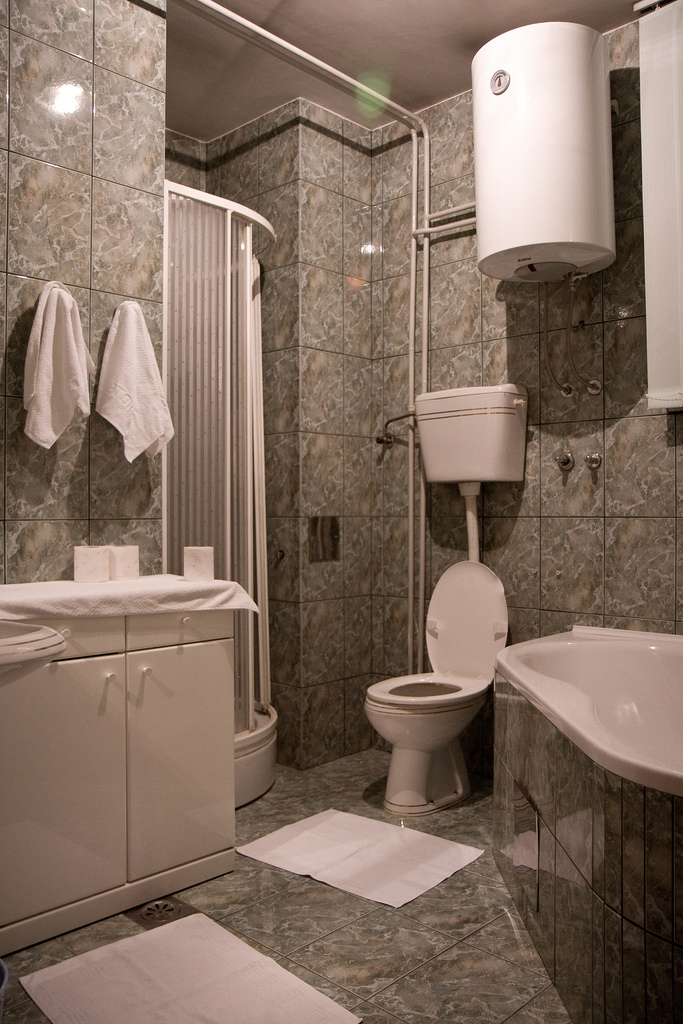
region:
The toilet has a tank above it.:
[361, 381, 528, 817]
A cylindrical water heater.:
[469, 21, 618, 284]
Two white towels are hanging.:
[22, 280, 174, 464]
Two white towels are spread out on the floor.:
[0, 747, 570, 1022]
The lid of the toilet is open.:
[362, 559, 508, 817]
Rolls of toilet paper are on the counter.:
[0, 542, 235, 956]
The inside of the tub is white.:
[493, 623, 680, 1022]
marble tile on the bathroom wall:
[600, 411, 674, 515]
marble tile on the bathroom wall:
[600, 512, 674, 619]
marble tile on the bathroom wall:
[535, 510, 604, 617]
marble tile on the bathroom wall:
[492, 514, 536, 612]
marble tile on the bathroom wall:
[294, 425, 346, 513]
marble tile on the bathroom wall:
[294, 510, 349, 599]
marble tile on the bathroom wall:
[299, 597, 338, 677]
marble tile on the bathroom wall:
[300, 678, 344, 763]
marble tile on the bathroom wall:
[294, 344, 345, 432]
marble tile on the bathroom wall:
[342, 350, 377, 440]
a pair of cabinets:
[3, 653, 254, 930]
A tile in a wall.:
[301, 343, 349, 436]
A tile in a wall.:
[297, 179, 351, 272]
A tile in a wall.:
[298, 126, 342, 186]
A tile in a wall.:
[336, 138, 379, 201]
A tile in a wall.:
[340, 194, 376, 277]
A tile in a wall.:
[337, 349, 370, 433]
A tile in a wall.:
[341, 435, 375, 515]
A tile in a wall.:
[343, 598, 371, 677]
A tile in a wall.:
[542, 511, 606, 612]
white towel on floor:
[209, 785, 512, 928]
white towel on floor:
[215, 779, 507, 932]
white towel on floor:
[216, 785, 510, 922]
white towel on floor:
[217, 790, 520, 925]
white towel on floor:
[222, 790, 510, 921]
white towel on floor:
[219, 791, 501, 925]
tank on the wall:
[398, 364, 547, 506]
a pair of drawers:
[13, 584, 242, 655]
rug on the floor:
[243, 779, 487, 921]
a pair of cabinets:
[3, 632, 256, 924]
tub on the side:
[491, 581, 679, 1003]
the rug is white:
[8, 901, 373, 1021]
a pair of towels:
[28, 272, 202, 468]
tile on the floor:
[258, 883, 518, 1017]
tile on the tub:
[467, 710, 631, 947]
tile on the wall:
[289, 122, 406, 666]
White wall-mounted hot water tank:
[469, 19, 612, 283]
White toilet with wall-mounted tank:
[360, 383, 525, 818]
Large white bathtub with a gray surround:
[496, 621, 682, 1021]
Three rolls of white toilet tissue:
[74, 544, 212, 579]